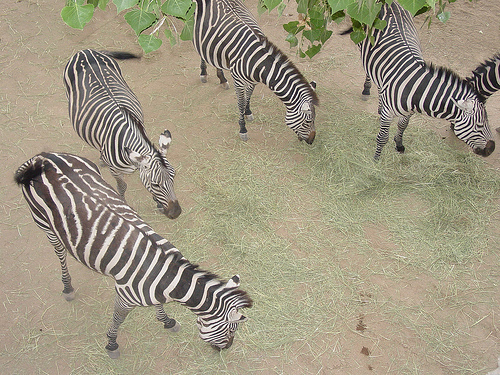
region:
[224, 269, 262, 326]
the zebra has ears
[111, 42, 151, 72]
the zebra has a tail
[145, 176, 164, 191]
the zebra has an eye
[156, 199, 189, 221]
the zebra has a nose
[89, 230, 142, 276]
the zebra has stripes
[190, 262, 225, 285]
the zebra has a main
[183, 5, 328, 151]
the zebra is eating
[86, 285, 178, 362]
the zebra has front legs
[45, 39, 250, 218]
the zebra is standing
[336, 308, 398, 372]
the spots are on the ground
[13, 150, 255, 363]
THIS IS A ZEBRA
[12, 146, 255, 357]
THE ZEBRA IS EATING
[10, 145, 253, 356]
THE ZEBRA IS STANDING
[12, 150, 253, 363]
THE ZEBRA HAS STRIPES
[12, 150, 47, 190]
THE ZEBRA HAS A TAIL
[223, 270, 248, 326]
THESE ARE EARS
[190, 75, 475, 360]
THIS IS DRIED GRASS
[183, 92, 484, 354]
THE HAY IS GREEN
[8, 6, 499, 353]
FOUR ZEBRAS TOGETHER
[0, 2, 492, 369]
THE HAY IS ON THE GROUND BENEATH THE ZEBRAS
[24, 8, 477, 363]
The zebras are eating hay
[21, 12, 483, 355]
The zebras are black and white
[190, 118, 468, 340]
The hay is green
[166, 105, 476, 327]
The hay is spread out over the ground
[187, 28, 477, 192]
The zebras are striped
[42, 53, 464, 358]
The ground is dirt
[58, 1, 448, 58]
Branches over the zebras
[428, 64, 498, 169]
Zebra with its ears back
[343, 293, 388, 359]
Water on the ground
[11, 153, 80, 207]
The zebra has a black tail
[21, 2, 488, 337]
A group of black and white animals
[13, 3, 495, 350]
A group of four zebra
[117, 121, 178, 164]
Two ears on a zebra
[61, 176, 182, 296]
Black and white stripes on a zebra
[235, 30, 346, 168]
A zebra eating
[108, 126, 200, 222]
The face of a zebra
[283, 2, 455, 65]
A zebra partially under a tree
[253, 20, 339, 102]
A mane down the neck of a zebra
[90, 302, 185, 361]
Two zebra legs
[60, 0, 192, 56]
Green leaves from on a tree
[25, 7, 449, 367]
a few animals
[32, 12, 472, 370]
some zebras grazing in a field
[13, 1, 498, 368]
a few black and white zebras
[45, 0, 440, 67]
some green leaves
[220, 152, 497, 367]
some hay on the ground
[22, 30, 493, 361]
a dirt ground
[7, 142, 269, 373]
a zebra eating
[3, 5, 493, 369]
a scene with some animals in it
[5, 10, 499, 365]
a scene happening during the day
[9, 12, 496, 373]
a scene outside